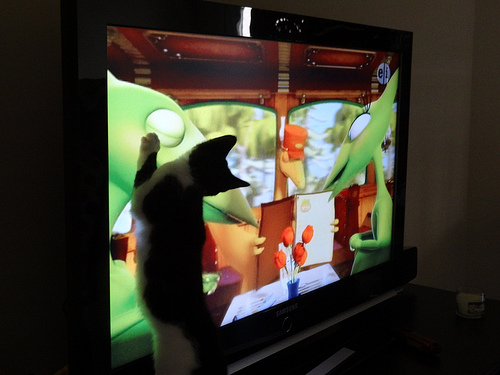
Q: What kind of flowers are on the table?
A: Roses.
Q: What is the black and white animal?
A: A cat.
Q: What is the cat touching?
A: Tv.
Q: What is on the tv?
A: Dinosaur show.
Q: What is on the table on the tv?
A: Flowers.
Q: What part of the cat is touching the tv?
A: Paw.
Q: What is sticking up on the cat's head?
A: Ear.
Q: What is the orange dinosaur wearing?
A: Hat.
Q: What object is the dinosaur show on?
A: Tv.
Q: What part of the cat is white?
A: Underside.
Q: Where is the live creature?
A: To the left, against the screen.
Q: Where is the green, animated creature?
A: On the side of the screen, opposite the cat.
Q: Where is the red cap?
A: On a billed, animated animal, seated with a menu, in front of flowers.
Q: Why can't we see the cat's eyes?
A: The back of the cat's head is facing the viewer.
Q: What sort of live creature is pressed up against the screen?
A: A cat.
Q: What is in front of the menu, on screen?
A: A vase with red flowers.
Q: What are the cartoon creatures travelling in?
A: A train.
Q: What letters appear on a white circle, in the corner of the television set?
A: E and I.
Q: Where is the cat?
A: Near the tv.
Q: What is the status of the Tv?
A: On.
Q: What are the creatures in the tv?
A: Dinosaurs.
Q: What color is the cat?
A: Black and white.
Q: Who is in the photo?
A: No one.